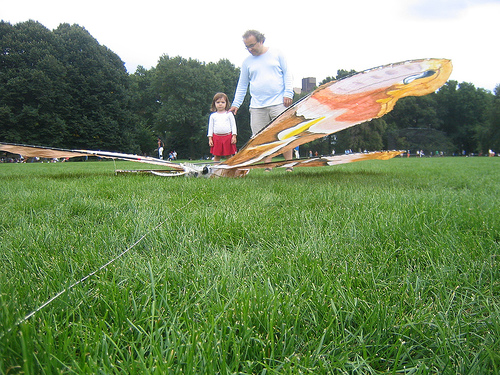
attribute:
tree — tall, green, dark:
[2, 16, 71, 156]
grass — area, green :
[9, 162, 496, 369]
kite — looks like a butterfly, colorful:
[2, 54, 452, 195]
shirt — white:
[189, 101, 239, 125]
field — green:
[2, 159, 498, 371]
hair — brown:
[208, 81, 232, 119]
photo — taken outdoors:
[4, 3, 499, 374]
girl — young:
[204, 88, 240, 163]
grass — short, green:
[108, 255, 378, 373]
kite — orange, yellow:
[205, 79, 443, 164]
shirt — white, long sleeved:
[176, 110, 245, 155]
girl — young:
[195, 85, 237, 169]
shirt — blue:
[233, 54, 288, 121]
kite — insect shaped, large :
[9, 49, 455, 177]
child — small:
[208, 90, 240, 167]